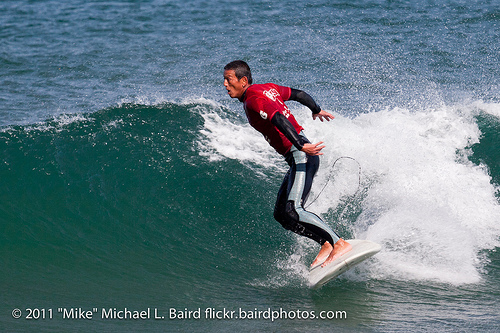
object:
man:
[223, 60, 352, 270]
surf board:
[309, 240, 383, 290]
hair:
[224, 60, 253, 84]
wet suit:
[242, 83, 340, 246]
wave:
[0, 90, 500, 291]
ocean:
[1, 1, 498, 329]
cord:
[304, 156, 362, 232]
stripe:
[288, 145, 340, 245]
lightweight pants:
[273, 149, 341, 246]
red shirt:
[242, 83, 304, 157]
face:
[224, 70, 243, 98]